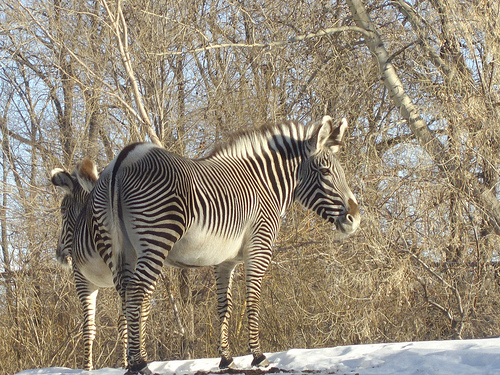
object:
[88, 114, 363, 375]
zebra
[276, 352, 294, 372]
snow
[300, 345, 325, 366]
snow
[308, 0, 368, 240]
trees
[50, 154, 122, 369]
zebras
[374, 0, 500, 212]
trees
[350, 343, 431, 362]
snow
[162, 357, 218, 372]
ground